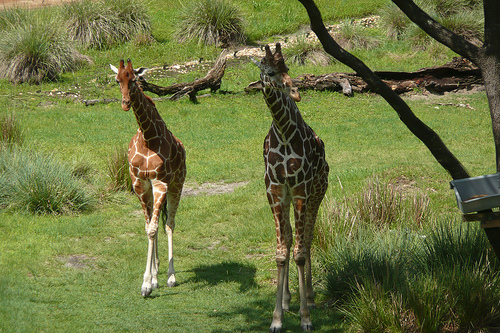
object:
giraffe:
[108, 58, 188, 298]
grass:
[0, 159, 96, 217]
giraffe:
[243, 42, 329, 332]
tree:
[298, 0, 500, 261]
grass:
[319, 173, 498, 333]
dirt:
[180, 179, 247, 197]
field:
[0, 0, 497, 332]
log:
[133, 48, 230, 105]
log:
[244, 56, 481, 98]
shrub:
[0, 0, 92, 86]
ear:
[109, 62, 119, 75]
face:
[262, 60, 302, 102]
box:
[448, 172, 500, 222]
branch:
[391, 0, 485, 66]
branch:
[297, 1, 470, 180]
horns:
[117, 59, 124, 69]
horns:
[272, 42, 286, 58]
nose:
[120, 97, 132, 106]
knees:
[145, 227, 157, 239]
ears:
[131, 67, 150, 79]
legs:
[160, 187, 182, 287]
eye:
[266, 69, 276, 77]